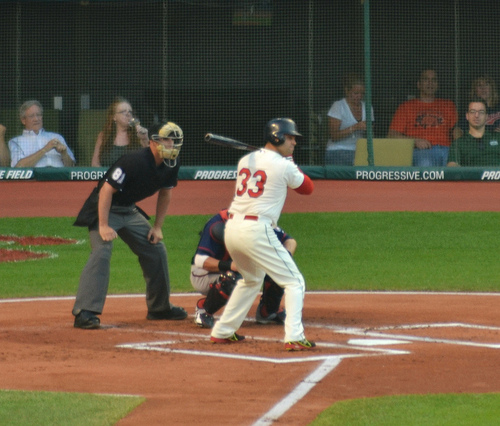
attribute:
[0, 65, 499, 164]
fans — watching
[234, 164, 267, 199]
33 — red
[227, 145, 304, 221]
shirt — white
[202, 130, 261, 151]
bat — black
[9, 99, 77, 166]
man — older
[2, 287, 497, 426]
stripes — white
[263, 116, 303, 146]
helmet — black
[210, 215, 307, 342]
pants — white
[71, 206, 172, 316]
pants — grey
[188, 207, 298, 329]
catcher — crouching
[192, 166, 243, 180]
progressive — sponsor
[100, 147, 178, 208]
shirt — black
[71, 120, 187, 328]
umpire — bent over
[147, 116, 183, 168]
helmet — yellow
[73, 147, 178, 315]
clothing — black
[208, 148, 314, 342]
uniform — white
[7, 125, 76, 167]
shirt — white, button down, butto dow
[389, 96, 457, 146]
t-shirt — orange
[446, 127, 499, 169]
shirt — green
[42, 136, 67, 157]
hands — together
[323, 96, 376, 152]
shirt — white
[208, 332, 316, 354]
cleats — multicolored